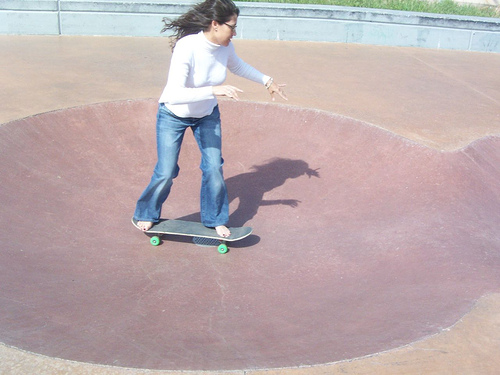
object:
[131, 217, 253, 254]
skateboard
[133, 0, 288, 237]
woman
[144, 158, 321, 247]
shadow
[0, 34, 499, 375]
ground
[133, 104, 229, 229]
jeans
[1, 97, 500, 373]
ramp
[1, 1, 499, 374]
skatepark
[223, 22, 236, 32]
glasses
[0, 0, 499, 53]
fence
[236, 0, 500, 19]
leaves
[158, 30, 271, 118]
sweater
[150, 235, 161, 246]
wheels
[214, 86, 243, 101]
right hand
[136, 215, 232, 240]
bare feet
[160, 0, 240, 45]
hair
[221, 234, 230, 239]
toes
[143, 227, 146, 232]
nail polish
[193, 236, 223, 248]
drain